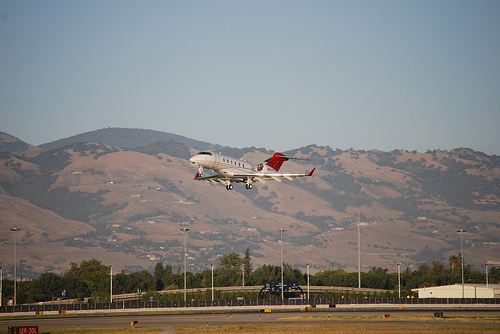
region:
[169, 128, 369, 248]
an aero plane flying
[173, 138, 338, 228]
a plane in air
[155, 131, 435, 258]
a plane near to ground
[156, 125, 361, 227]
a plane trying to get down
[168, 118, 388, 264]
a plane trying to fly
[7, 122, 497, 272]
a beautiful view of mountain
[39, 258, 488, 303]
a group of pillars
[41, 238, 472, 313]
a group of electric poles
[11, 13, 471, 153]
a beautiful view of sky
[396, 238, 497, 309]
a small white home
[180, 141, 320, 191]
airplane in the sky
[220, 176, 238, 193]
landing gear on an airplane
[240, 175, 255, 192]
landing gear on an airplane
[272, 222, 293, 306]
outdoor light on a pole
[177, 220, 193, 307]
outdoor light on a pole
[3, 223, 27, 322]
outdoor light on a pole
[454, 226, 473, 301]
outdoor light on a pole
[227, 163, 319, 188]
wing of a plane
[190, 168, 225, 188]
wing of a plane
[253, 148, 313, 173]
tail of a plane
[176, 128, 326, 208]
a plane above the area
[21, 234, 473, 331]
the airfield for aircraft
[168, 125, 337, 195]
the plane is white with red trim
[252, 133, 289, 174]
the tail is red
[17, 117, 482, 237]
mountains in the area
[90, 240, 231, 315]
lights on the airfiled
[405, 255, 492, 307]
a white structure in the shot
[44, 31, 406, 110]
a hazy blue sky above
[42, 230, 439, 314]
trees in the area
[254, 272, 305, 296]
a blue sign on a building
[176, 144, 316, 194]
white and red plane flying low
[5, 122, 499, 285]
mountainside behind the airplane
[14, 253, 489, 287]
line of trees beside the runway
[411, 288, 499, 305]
white building at the airport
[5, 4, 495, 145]
blue gray sky above mountaintops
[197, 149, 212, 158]
front windows of white airplane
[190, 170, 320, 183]
white wings with red tips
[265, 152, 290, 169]
red tail of white airplane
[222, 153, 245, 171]
row of windows on plane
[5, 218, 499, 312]
lights on poles on the runway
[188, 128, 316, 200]
a large silver and red plane flying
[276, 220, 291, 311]
a very tall light pole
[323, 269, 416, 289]
some trees in the distance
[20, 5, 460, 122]
a very clear sky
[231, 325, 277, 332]
some grass on the runway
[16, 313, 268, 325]
air plane run way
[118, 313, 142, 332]
some lights on the runway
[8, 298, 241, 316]
a fence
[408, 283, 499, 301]
a small air plane hangar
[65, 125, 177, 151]
a large mountain in the distance